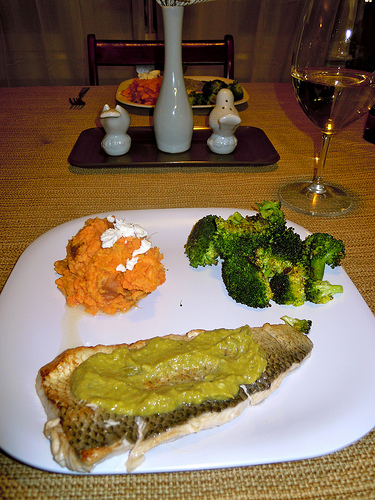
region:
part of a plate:
[277, 427, 303, 460]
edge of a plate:
[240, 434, 285, 487]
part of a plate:
[272, 390, 306, 445]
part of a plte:
[257, 425, 292, 476]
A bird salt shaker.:
[210, 83, 244, 151]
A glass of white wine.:
[295, 7, 368, 217]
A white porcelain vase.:
[150, 5, 197, 157]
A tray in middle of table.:
[69, 122, 277, 171]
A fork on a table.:
[63, 81, 93, 109]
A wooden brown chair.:
[86, 26, 235, 83]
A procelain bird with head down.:
[95, 105, 130, 151]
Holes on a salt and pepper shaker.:
[219, 97, 235, 112]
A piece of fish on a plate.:
[38, 321, 345, 454]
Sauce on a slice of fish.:
[72, 327, 269, 406]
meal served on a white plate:
[1, 194, 369, 475]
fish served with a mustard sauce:
[32, 321, 314, 469]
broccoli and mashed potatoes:
[54, 199, 347, 314]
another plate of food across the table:
[113, 68, 250, 107]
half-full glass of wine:
[276, 0, 373, 216]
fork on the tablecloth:
[64, 85, 92, 106]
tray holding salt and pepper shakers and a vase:
[64, 124, 280, 169]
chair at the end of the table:
[84, 32, 236, 87]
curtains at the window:
[1, 0, 373, 83]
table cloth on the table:
[1, 85, 373, 498]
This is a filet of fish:
[67, 282, 356, 486]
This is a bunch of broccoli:
[165, 203, 372, 298]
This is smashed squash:
[58, 208, 180, 309]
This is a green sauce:
[71, 353, 219, 394]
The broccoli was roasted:
[204, 213, 337, 343]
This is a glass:
[280, 172, 357, 214]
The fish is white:
[75, 430, 92, 460]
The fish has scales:
[66, 418, 103, 456]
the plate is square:
[31, 204, 364, 465]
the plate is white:
[27, 203, 367, 477]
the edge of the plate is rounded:
[28, 203, 121, 244]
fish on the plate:
[39, 317, 334, 449]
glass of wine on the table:
[291, 20, 363, 220]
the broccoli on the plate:
[185, 201, 343, 322]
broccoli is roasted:
[190, 208, 331, 316]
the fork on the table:
[69, 85, 93, 106]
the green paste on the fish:
[66, 328, 280, 401]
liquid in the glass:
[276, 55, 374, 141]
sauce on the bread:
[29, 304, 319, 451]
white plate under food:
[282, 378, 348, 435]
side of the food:
[70, 309, 271, 367]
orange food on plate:
[38, 212, 186, 321]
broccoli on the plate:
[148, 196, 347, 332]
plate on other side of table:
[93, 51, 268, 135]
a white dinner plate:
[13, 190, 373, 481]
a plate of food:
[21, 191, 370, 486]